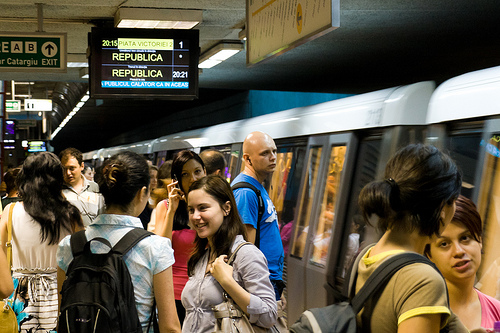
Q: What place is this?
A: It is a station.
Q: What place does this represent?
A: It represents the station.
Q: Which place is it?
A: It is a station.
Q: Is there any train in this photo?
A: Yes, there is a train.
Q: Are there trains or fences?
A: Yes, there is a train.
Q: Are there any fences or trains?
A: Yes, there is a train.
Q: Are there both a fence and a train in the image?
A: No, there is a train but no fences.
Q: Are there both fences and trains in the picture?
A: No, there is a train but no fences.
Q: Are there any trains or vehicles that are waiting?
A: Yes, the train is waiting.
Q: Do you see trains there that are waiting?
A: Yes, there is a train that is waiting.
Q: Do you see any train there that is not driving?
A: Yes, there is a train that is waiting .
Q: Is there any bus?
A: No, there are no buses.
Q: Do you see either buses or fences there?
A: No, there are no buses or fences.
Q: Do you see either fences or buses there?
A: No, there are no buses or fences.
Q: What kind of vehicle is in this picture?
A: The vehicle is a train.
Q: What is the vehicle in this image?
A: The vehicle is a train.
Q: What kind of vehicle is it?
A: The vehicle is a train.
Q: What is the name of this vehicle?
A: This is a train.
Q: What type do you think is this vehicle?
A: This is a train.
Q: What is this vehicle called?
A: This is a train.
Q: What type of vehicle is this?
A: This is a train.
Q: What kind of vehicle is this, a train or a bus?
A: This is a train.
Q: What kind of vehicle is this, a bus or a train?
A: This is a train.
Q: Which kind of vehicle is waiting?
A: The vehicle is a train.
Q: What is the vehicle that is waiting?
A: The vehicle is a train.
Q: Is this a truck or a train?
A: This is a train.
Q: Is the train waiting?
A: Yes, the train is waiting.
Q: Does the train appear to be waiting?
A: Yes, the train is waiting.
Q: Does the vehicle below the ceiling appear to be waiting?
A: Yes, the train is waiting.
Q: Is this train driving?
A: No, the train is waiting.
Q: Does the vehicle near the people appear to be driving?
A: No, the train is waiting.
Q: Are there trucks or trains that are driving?
A: No, there is a train but it is waiting.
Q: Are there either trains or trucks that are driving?
A: No, there is a train but it is waiting.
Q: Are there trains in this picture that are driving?
A: No, there is a train but it is waiting.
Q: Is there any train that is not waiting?
A: No, there is a train but it is waiting.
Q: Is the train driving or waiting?
A: The train is waiting.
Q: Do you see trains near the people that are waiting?
A: Yes, there is a train near the people.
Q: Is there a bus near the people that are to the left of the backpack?
A: No, there is a train near the people.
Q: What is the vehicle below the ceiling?
A: The vehicle is a train.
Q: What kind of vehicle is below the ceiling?
A: The vehicle is a train.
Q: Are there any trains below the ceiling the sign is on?
A: Yes, there is a train below the ceiling.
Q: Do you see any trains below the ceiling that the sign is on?
A: Yes, there is a train below the ceiling.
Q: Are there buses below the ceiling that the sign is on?
A: No, there is a train below the ceiling.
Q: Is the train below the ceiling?
A: Yes, the train is below the ceiling.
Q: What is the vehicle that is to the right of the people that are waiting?
A: The vehicle is a train.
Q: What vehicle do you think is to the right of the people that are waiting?
A: The vehicle is a train.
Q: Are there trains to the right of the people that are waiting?
A: Yes, there is a train to the right of the people.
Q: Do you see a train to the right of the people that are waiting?
A: Yes, there is a train to the right of the people.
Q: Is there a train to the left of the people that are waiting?
A: No, the train is to the right of the people.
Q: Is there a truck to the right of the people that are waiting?
A: No, there is a train to the right of the people.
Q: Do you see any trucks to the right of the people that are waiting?
A: No, there is a train to the right of the people.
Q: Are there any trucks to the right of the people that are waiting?
A: No, there is a train to the right of the people.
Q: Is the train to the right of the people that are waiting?
A: Yes, the train is to the right of the people.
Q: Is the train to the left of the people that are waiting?
A: No, the train is to the right of the people.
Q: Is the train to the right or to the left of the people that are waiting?
A: The train is to the right of the people.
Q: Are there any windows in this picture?
A: Yes, there is a window.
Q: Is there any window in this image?
A: Yes, there is a window.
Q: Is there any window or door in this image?
A: Yes, there is a window.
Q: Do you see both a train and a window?
A: Yes, there are both a window and a train.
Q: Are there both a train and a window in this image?
A: Yes, there are both a window and a train.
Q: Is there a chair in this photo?
A: No, there are no chairs.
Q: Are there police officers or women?
A: Yes, there is a woman.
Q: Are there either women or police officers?
A: Yes, there is a woman.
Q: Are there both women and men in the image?
A: Yes, there are both a woman and a man.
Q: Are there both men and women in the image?
A: Yes, there are both a woman and a man.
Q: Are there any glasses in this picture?
A: No, there are no glasses.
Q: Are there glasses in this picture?
A: No, there are no glasses.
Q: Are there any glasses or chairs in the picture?
A: No, there are no glasses or chairs.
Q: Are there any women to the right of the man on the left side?
A: Yes, there is a woman to the right of the man.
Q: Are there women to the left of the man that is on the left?
A: No, the woman is to the right of the man.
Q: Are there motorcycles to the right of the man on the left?
A: No, there is a woman to the right of the man.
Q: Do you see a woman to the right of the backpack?
A: Yes, there is a woman to the right of the backpack.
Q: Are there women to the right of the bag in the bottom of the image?
A: Yes, there is a woman to the right of the backpack.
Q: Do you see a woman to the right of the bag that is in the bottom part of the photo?
A: Yes, there is a woman to the right of the backpack.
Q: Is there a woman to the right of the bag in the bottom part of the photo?
A: Yes, there is a woman to the right of the backpack.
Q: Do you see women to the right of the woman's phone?
A: Yes, there is a woman to the right of the telephone.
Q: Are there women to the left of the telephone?
A: No, the woman is to the right of the telephone.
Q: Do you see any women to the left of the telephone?
A: No, the woman is to the right of the telephone.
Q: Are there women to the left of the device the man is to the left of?
A: No, the woman is to the right of the telephone.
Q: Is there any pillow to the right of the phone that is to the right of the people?
A: No, there is a woman to the right of the phone.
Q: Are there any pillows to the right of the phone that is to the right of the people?
A: No, there is a woman to the right of the phone.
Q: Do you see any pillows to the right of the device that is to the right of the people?
A: No, there is a woman to the right of the phone.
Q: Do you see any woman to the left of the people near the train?
A: No, the woman is to the right of the people.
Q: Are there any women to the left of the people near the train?
A: No, the woman is to the right of the people.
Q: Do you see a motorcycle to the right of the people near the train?
A: No, there is a woman to the right of the people.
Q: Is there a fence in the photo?
A: No, there are no fences.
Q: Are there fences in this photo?
A: No, there are no fences.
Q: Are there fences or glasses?
A: No, there are no fences or glasses.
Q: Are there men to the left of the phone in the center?
A: Yes, there is a man to the left of the telephone.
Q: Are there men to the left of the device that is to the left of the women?
A: Yes, there is a man to the left of the telephone.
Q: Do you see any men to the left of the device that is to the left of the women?
A: Yes, there is a man to the left of the telephone.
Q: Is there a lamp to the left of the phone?
A: No, there is a man to the left of the phone.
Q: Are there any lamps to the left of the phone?
A: No, there is a man to the left of the phone.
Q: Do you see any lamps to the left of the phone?
A: No, there is a man to the left of the phone.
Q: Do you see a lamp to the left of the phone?
A: No, there is a man to the left of the phone.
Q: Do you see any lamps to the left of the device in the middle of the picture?
A: No, there is a man to the left of the phone.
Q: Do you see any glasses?
A: No, there are no glasses.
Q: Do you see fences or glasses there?
A: No, there are no glasses or fences.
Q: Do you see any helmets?
A: No, there are no helmets.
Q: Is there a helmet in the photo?
A: No, there are no helmets.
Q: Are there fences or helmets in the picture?
A: No, there are no helmets or fences.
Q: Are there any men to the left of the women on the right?
A: Yes, there is a man to the left of the women.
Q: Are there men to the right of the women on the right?
A: No, the man is to the left of the women.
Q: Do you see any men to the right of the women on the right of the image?
A: No, the man is to the left of the women.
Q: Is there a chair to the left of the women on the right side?
A: No, there is a man to the left of the women.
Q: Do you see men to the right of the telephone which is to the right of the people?
A: Yes, there is a man to the right of the telephone.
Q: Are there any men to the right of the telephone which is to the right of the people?
A: Yes, there is a man to the right of the telephone.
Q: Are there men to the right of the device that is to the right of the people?
A: Yes, there is a man to the right of the telephone.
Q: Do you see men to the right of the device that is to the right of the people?
A: Yes, there is a man to the right of the telephone.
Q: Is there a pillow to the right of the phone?
A: No, there is a man to the right of the phone.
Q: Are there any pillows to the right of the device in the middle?
A: No, there is a man to the right of the phone.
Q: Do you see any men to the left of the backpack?
A: No, the man is to the right of the backpack.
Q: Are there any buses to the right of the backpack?
A: No, there is a man to the right of the backpack.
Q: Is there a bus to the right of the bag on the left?
A: No, there is a man to the right of the backpack.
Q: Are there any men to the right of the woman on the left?
A: Yes, there is a man to the right of the woman.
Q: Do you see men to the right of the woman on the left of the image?
A: Yes, there is a man to the right of the woman.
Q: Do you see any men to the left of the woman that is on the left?
A: No, the man is to the right of the woman.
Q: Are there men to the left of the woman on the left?
A: No, the man is to the right of the woman.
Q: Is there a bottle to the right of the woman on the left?
A: No, there is a man to the right of the woman.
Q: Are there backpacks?
A: Yes, there is a backpack.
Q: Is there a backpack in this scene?
A: Yes, there is a backpack.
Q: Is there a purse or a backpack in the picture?
A: Yes, there is a backpack.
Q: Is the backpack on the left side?
A: Yes, the backpack is on the left of the image.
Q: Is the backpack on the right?
A: No, the backpack is on the left of the image.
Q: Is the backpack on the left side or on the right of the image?
A: The backpack is on the left of the image.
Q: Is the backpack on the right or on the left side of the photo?
A: The backpack is on the left of the image.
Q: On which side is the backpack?
A: The backpack is on the left of the image.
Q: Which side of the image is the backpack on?
A: The backpack is on the left of the image.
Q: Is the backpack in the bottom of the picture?
A: Yes, the backpack is in the bottom of the image.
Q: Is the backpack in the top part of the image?
A: No, the backpack is in the bottom of the image.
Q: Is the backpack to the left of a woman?
A: Yes, the backpack is to the left of a woman.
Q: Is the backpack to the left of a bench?
A: No, the backpack is to the left of a woman.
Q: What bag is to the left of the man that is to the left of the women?
A: The bag is a backpack.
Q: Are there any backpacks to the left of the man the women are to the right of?
A: Yes, there is a backpack to the left of the man.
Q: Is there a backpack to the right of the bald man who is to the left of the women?
A: No, the backpack is to the left of the man.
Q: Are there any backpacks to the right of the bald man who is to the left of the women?
A: No, the backpack is to the left of the man.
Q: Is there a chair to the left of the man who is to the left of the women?
A: No, there is a backpack to the left of the man.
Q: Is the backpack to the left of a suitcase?
A: No, the backpack is to the left of a man.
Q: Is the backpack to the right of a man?
A: No, the backpack is to the left of a man.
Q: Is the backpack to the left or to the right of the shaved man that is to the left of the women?
A: The backpack is to the left of the man.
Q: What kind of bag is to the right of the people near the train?
A: The bag is a backpack.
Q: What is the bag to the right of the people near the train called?
A: The bag is a backpack.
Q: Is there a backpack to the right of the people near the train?
A: Yes, there is a backpack to the right of the people.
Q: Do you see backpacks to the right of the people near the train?
A: Yes, there is a backpack to the right of the people.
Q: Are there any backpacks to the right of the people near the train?
A: Yes, there is a backpack to the right of the people.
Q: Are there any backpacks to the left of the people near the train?
A: No, the backpack is to the right of the people.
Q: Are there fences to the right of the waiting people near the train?
A: No, there is a backpack to the right of the people.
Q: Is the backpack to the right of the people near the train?
A: Yes, the backpack is to the right of the people.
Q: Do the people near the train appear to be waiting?
A: Yes, the people are waiting.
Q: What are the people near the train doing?
A: The people are waiting.